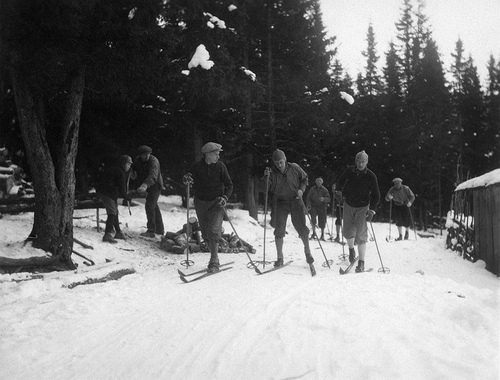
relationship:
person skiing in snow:
[331, 148, 381, 272] [1, 194, 499, 380]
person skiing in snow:
[256, 148, 314, 268] [1, 194, 499, 380]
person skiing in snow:
[183, 141, 235, 274] [1, 194, 499, 380]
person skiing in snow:
[384, 178, 415, 241] [1, 194, 499, 380]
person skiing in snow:
[306, 175, 332, 240] [1, 194, 499, 380]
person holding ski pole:
[331, 148, 381, 272] [370, 222, 390, 275]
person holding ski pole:
[331, 148, 381, 272] [336, 200, 350, 262]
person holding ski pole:
[256, 148, 314, 268] [300, 197, 334, 270]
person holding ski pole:
[256, 148, 314, 268] [256, 167, 273, 270]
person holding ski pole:
[183, 141, 235, 274] [222, 206, 261, 272]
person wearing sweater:
[183, 141, 235, 274] [184, 156, 234, 203]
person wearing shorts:
[331, 148, 381, 272] [341, 202, 369, 246]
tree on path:
[0, 0, 188, 273] [1, 215, 499, 379]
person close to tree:
[97, 154, 133, 243] [0, 0, 188, 273]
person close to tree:
[130, 145, 165, 239] [0, 0, 188, 273]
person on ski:
[183, 141, 235, 274] [177, 261, 234, 278]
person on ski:
[256, 148, 314, 268] [256, 261, 291, 275]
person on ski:
[331, 148, 381, 272] [354, 267, 372, 273]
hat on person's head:
[200, 141, 223, 155] [201, 141, 223, 165]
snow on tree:
[186, 43, 216, 71] [140, 1, 257, 165]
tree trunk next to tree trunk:
[193, 126, 205, 163] [244, 153, 259, 221]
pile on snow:
[159, 216, 257, 255] [1, 194, 499, 380]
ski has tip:
[177, 261, 234, 278] [179, 274, 190, 282]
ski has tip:
[256, 261, 291, 275] [255, 268, 264, 274]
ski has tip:
[339, 255, 359, 275] [340, 268, 348, 276]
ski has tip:
[177, 261, 234, 278] [177, 269, 188, 276]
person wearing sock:
[331, 148, 381, 272] [347, 237, 355, 248]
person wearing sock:
[331, 148, 381, 272] [358, 243, 366, 263]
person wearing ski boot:
[331, 148, 381, 272] [348, 247, 356, 262]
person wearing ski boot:
[331, 148, 381, 272] [356, 260, 365, 272]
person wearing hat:
[183, 141, 235, 274] [200, 141, 223, 155]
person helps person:
[97, 154, 133, 243] [130, 145, 165, 239]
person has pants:
[130, 145, 165, 239] [145, 182, 165, 234]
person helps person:
[130, 145, 165, 239] [97, 154, 133, 243]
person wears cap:
[130, 145, 165, 239] [135, 145, 153, 156]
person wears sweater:
[183, 141, 235, 274] [184, 156, 234, 203]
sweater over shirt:
[184, 156, 234, 203] [201, 159, 215, 176]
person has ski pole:
[256, 148, 314, 268] [256, 167, 273, 270]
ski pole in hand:
[256, 167, 273, 270] [263, 167, 271, 177]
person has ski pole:
[256, 148, 314, 268] [300, 197, 334, 270]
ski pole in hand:
[300, 197, 334, 270] [297, 190, 304, 199]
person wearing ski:
[256, 148, 314, 268] [256, 261, 291, 275]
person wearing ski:
[256, 148, 314, 268] [308, 263, 316, 277]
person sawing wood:
[97, 154, 133, 243] [0, 190, 149, 206]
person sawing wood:
[130, 145, 165, 239] [0, 190, 149, 206]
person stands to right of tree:
[97, 154, 133, 243] [0, 0, 188, 273]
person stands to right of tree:
[130, 145, 165, 239] [0, 0, 188, 273]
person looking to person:
[183, 141, 235, 274] [256, 148, 314, 268]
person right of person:
[256, 148, 314, 268] [183, 141, 235, 274]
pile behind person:
[159, 216, 257, 255] [183, 141, 235, 274]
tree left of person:
[0, 0, 188, 273] [183, 141, 235, 274]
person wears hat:
[183, 141, 235, 274] [200, 141, 223, 155]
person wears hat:
[256, 148, 314, 268] [271, 147, 287, 165]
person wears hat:
[331, 148, 381, 272] [354, 149, 369, 166]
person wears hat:
[97, 154, 133, 243] [117, 154, 133, 169]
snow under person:
[1, 194, 499, 380] [183, 141, 235, 274]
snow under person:
[1, 194, 499, 380] [256, 148, 314, 268]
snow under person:
[1, 194, 499, 380] [331, 148, 381, 272]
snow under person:
[1, 194, 499, 380] [306, 175, 332, 240]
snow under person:
[1, 194, 499, 380] [384, 178, 415, 241]